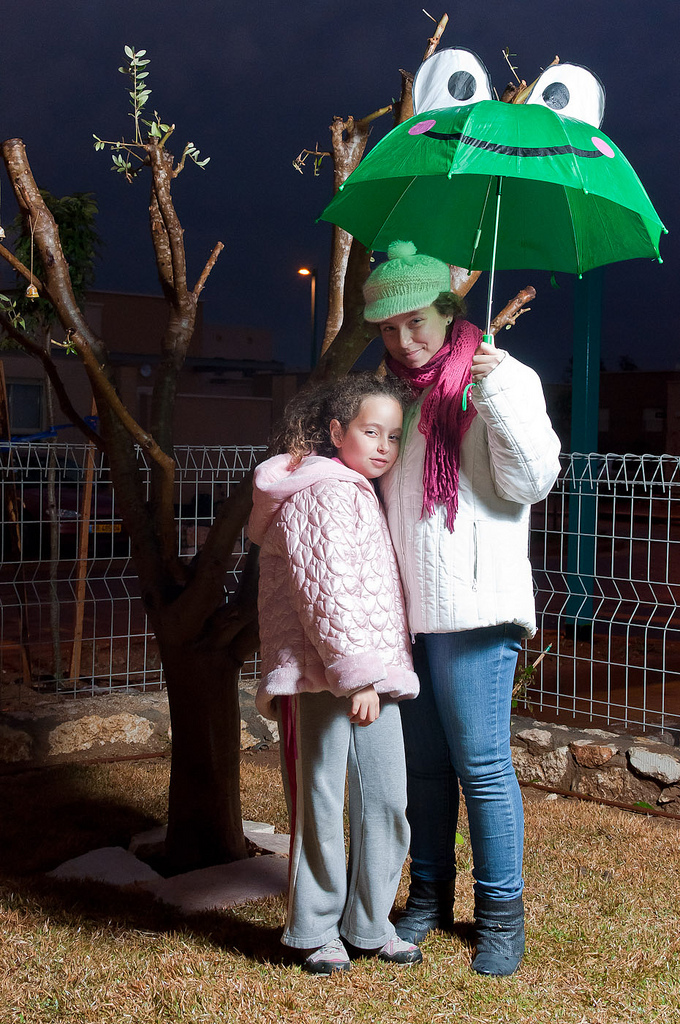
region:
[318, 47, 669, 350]
open green frog umbrella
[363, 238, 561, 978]
woman is holding an umbrella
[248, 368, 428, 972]
young girl hugging her mother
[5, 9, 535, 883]
tree with very few leaves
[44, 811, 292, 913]
cement landscaping around base of tree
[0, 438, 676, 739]
metal fence around a yard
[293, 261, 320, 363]
tall streetlight is on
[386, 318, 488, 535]
pink scarf around a neck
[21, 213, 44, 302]
small bell hanging from the tree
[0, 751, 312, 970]
shadow of tree on the ground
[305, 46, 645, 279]
green umbrella with eyeballs and smile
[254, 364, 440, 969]
young girl standing next to mother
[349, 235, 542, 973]
mother holding an umbrella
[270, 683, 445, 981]
grey sweatpants on the girl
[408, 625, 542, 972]
tight jeans on the woman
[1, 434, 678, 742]
wire fence with 90 degree bend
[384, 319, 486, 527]
bright pink scarf on woman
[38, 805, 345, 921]
cement around the tree base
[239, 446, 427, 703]
pink hooded jacket on girl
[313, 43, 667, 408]
woman is holding an umbrella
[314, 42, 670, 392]
umbrella looks like a frog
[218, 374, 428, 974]
girl is wearing a pink coat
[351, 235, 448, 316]
woman is wearing a hat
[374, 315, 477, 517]
woman has a pink scarf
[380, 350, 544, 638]
woman is wearing a white jacket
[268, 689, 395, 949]
girl is wearing grey pants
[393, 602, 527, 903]
woman is wearing blue jeans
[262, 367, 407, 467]
girl has curly hair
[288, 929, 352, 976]
girl has grey shoe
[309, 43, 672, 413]
A froggy green umbrella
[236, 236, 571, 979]
Woman and young girl in warm clothing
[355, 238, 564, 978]
Woman in blue jeans wearing black boots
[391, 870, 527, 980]
Leather black boots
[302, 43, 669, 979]
Woman holding a green umbrella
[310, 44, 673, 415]
Green umbrella has froggy design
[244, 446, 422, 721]
Pink hooded jacket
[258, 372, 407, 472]
Brown curly hair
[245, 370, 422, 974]
Child has brown curly hair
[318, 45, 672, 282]
green frog design umbrella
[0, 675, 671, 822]
flagstone and concrete curb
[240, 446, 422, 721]
hooded pink fur-trimmed jacket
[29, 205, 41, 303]
hanging bell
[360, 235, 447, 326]
knitted cap with pom pom on top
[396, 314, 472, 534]
pink wrap around scarf with fringe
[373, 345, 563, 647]
zippered insulated jacket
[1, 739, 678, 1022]
winter lawn of dead grass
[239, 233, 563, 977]
woman and young girl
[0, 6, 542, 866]
bare branched tree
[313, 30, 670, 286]
a green umbrella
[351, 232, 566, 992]
a woman wearing a red scarf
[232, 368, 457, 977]
a girl leaning against a woman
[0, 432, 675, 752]
a fence behind the people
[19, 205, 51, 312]
a bell hanging on the tree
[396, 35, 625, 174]
frog face on the green umbrella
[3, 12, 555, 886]
a tree with cut branches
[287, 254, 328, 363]
a light on a pole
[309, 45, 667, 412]
A green frog umbrella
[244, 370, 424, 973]
A girl in a pink coat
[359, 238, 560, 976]
woman in a white coat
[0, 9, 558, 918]
brown tree surrounded by stone